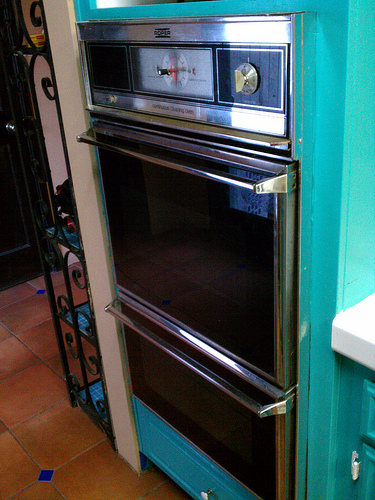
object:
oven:
[89, 119, 315, 382]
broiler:
[120, 296, 285, 499]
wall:
[81, 0, 375, 500]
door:
[123, 315, 278, 499]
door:
[90, 127, 286, 384]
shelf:
[13, 1, 117, 450]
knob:
[234, 62, 258, 96]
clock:
[143, 51, 209, 94]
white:
[358, 312, 374, 335]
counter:
[331, 294, 375, 375]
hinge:
[349, 449, 361, 483]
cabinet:
[349, 365, 375, 499]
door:
[359, 447, 374, 500]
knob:
[5, 115, 19, 132]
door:
[3, 4, 56, 289]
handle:
[78, 136, 257, 194]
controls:
[86, 42, 285, 112]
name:
[153, 27, 173, 39]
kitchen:
[4, 0, 373, 499]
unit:
[74, 20, 305, 498]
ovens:
[88, 113, 292, 497]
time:
[170, 56, 179, 87]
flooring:
[0, 266, 189, 499]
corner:
[42, 0, 142, 475]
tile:
[40, 467, 54, 484]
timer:
[156, 53, 196, 92]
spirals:
[77, 333, 101, 379]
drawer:
[137, 401, 266, 499]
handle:
[197, 485, 211, 499]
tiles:
[66, 300, 95, 338]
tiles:
[44, 215, 81, 250]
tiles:
[77, 374, 111, 431]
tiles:
[7, 395, 108, 478]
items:
[49, 183, 77, 244]